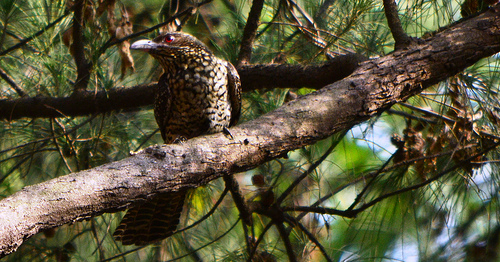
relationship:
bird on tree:
[102, 27, 249, 251] [5, 1, 494, 251]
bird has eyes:
[102, 27, 249, 251] [160, 29, 179, 42]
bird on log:
[102, 27, 249, 251] [0, 3, 493, 260]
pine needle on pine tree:
[405, 170, 422, 260] [1, 0, 498, 260]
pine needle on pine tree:
[352, 137, 394, 156] [1, 0, 498, 260]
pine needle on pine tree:
[486, 147, 494, 248] [1, 0, 498, 260]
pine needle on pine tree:
[347, 255, 403, 260] [1, 0, 498, 260]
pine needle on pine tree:
[432, 0, 440, 30] [1, 0, 498, 260]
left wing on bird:
[151, 74, 173, 130] [102, 27, 249, 251]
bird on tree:
[111, 207, 194, 247] [5, 1, 494, 251]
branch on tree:
[2, 0, 497, 259] [5, 1, 494, 251]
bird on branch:
[128, 12, 244, 127] [211, 45, 428, 202]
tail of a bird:
[103, 178, 208, 250] [111, 207, 194, 247]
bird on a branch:
[111, 207, 194, 247] [2, 0, 497, 259]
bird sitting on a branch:
[111, 207, 194, 247] [2, 0, 497, 259]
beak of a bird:
[125, 37, 162, 53] [111, 207, 194, 247]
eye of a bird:
[161, 31, 182, 45] [102, 27, 249, 251]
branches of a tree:
[86, 153, 213, 185] [5, 1, 494, 251]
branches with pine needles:
[1, 0, 499, 259] [272, 162, 399, 242]